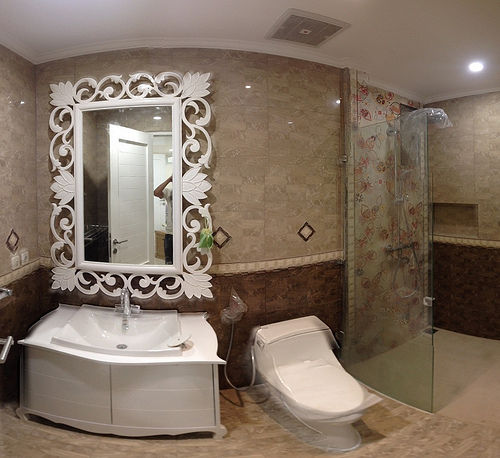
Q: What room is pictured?
A: It is a bathroom.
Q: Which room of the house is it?
A: It is a bathroom.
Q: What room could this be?
A: It is a bathroom.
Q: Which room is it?
A: It is a bathroom.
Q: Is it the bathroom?
A: Yes, it is the bathroom.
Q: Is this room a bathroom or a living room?
A: It is a bathroom.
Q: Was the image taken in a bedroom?
A: No, the picture was taken in a bathroom.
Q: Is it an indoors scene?
A: Yes, it is indoors.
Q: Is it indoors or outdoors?
A: It is indoors.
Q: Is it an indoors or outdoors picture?
A: It is indoors.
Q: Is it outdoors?
A: No, it is indoors.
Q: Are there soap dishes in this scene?
A: No, there are no soap dishes.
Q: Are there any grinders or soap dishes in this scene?
A: No, there are no soap dishes or grinders.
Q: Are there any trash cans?
A: No, there are no trash cans.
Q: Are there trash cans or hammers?
A: No, there are no trash cans or hammers.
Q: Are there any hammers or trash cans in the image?
A: No, there are no trash cans or hammers.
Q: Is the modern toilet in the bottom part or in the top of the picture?
A: The toilet is in the bottom of the image.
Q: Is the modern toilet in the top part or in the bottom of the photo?
A: The toilet is in the bottom of the image.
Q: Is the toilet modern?
A: Yes, the toilet is modern.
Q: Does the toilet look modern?
A: Yes, the toilet is modern.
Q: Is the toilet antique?
A: No, the toilet is modern.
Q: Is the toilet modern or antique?
A: The toilet is modern.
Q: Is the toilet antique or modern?
A: The toilet is modern.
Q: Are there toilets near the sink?
A: Yes, there is a toilet near the sink.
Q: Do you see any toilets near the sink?
A: Yes, there is a toilet near the sink.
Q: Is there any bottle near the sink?
A: No, there is a toilet near the sink.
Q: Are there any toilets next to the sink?
A: Yes, there is a toilet next to the sink.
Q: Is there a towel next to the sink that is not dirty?
A: No, there is a toilet next to the sink.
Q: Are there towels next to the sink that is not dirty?
A: No, there is a toilet next to the sink.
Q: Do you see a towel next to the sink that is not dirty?
A: No, there is a toilet next to the sink.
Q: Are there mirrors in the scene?
A: Yes, there is a mirror.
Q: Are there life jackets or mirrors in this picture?
A: Yes, there is a mirror.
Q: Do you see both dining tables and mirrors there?
A: No, there is a mirror but no dining tables.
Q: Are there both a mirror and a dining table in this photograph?
A: No, there is a mirror but no dining tables.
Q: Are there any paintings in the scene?
A: No, there are no paintings.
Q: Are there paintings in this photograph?
A: No, there are no paintings.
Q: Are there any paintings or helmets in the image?
A: No, there are no paintings or helmets.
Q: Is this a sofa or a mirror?
A: This is a mirror.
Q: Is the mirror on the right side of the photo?
A: No, the mirror is on the left of the image.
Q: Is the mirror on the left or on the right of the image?
A: The mirror is on the left of the image.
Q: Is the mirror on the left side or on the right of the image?
A: The mirror is on the left of the image.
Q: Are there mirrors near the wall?
A: Yes, there is a mirror near the wall.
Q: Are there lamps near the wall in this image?
A: No, there is a mirror near the wall.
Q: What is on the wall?
A: The mirror is on the wall.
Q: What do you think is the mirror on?
A: The mirror is on the wall.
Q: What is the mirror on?
A: The mirror is on the wall.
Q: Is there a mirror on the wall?
A: Yes, there is a mirror on the wall.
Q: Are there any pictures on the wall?
A: No, there is a mirror on the wall.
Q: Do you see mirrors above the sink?
A: Yes, there is a mirror above the sink.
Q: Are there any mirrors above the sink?
A: Yes, there is a mirror above the sink.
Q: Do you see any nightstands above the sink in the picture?
A: No, there is a mirror above the sink.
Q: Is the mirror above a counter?
A: No, the mirror is above a sink.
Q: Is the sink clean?
A: Yes, the sink is clean.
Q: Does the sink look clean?
A: Yes, the sink is clean.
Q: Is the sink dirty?
A: No, the sink is clean.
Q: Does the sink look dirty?
A: No, the sink is clean.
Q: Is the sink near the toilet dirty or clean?
A: The sink is clean.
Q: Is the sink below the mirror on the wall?
A: Yes, the sink is below the mirror.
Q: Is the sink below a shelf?
A: No, the sink is below the mirror.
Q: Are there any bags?
A: Yes, there is a bag.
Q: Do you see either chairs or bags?
A: Yes, there is a bag.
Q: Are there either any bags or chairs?
A: Yes, there is a bag.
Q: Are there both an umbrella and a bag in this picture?
A: No, there is a bag but no umbrellas.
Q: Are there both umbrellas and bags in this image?
A: No, there is a bag but no umbrellas.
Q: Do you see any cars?
A: No, there are no cars.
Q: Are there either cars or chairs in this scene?
A: No, there are no cars or chairs.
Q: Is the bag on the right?
A: Yes, the bag is on the right of the image.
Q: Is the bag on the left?
A: No, the bag is on the right of the image.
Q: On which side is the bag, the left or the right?
A: The bag is on the right of the image.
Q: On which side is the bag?
A: The bag is on the right of the image.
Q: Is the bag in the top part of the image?
A: Yes, the bag is in the top of the image.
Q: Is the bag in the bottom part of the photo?
A: No, the bag is in the top of the image.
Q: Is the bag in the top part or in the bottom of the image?
A: The bag is in the top of the image.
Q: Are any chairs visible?
A: No, there are no chairs.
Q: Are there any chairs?
A: No, there are no chairs.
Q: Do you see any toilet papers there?
A: No, there are no toilet papers.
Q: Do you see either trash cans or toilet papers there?
A: No, there are no toilet papers or trash cans.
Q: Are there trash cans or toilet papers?
A: No, there are no toilet papers or trash cans.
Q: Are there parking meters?
A: No, there are no parking meters.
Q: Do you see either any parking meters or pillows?
A: No, there are no parking meters or pillows.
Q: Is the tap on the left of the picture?
A: Yes, the tap is on the left of the image.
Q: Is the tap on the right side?
A: No, the tap is on the left of the image.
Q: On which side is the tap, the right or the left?
A: The tap is on the left of the image.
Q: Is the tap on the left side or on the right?
A: The tap is on the left of the image.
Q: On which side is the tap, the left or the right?
A: The tap is on the left of the image.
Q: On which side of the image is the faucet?
A: The faucet is on the left of the image.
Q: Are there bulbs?
A: No, there are no bulbs.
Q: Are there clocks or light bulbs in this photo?
A: No, there are no light bulbs or clocks.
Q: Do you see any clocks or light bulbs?
A: No, there are no light bulbs or clocks.